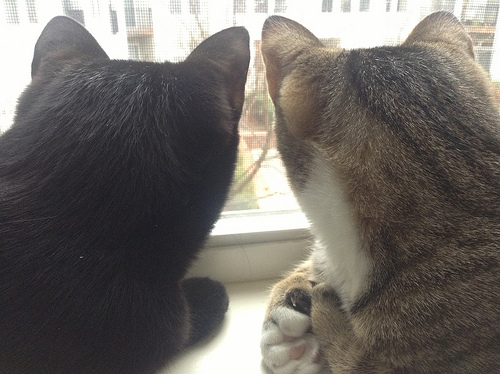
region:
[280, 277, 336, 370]
cat with paws together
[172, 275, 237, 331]
small black cat paw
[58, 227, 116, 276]
small white object on cat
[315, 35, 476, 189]
cat with 3 black stripes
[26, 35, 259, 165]
black cat with 2 ears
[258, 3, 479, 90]
brown cat with 2 ears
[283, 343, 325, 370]
small pink paw padding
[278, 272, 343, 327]
brown and black on paw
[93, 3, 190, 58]
doors and windows in back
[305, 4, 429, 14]
a few windows on building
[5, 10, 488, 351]
Looking out the window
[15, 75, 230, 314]
This cat is black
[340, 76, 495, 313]
this cat is tan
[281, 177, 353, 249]
the cat has a white neck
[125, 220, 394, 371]
curled up next to the window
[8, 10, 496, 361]
two cats looking out the window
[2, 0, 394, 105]
Building outside the window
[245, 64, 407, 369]
the cat is two colors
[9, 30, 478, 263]
Cats looking out the window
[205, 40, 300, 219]
tree outside the window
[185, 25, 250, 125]
a black cat's right ear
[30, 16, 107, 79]
a black cat's left ear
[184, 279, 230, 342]
a black cat's right paw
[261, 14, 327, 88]
a brown cat's left ear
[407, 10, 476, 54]
a brown cat's right ear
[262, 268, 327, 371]
a brown cat's paws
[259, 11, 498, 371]
a brown cat with white throat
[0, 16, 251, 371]
a furry black cat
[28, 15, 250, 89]
a black cat's ears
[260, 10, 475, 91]
a brown cat's ears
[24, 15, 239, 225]
blackcat looking out the window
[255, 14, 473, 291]
brown cat looking out the window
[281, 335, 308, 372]
pink paw pad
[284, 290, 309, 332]
sharp cat claw poking out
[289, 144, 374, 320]
cat has a white chin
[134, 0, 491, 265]
large window faces outside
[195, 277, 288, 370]
white ledge by window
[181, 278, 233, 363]
paw of the black cat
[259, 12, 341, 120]
cats ear has long hairs on top